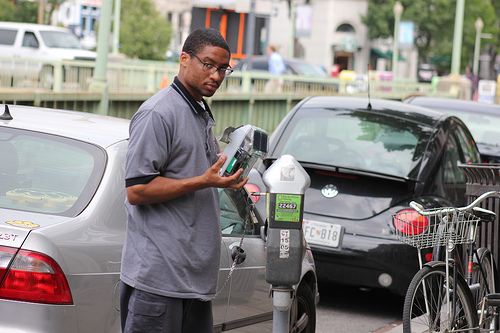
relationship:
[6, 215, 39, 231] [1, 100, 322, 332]
paw sticker on trunk of car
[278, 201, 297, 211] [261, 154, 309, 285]
numbers on front of parking meter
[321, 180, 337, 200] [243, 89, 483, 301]
logo on back of car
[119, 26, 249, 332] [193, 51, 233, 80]
man wearing glasses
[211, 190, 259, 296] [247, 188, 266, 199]
chain attached to key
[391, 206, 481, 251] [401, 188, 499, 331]
basket on front of bicycle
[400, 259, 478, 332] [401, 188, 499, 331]
tire on bottom of bicycle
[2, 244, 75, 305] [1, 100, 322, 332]
taillight on back of car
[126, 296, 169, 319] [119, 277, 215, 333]
pocket flap on side of pants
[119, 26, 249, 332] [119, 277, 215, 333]
man wearing pants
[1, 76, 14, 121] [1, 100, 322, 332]
antenna on top of car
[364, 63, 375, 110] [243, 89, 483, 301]
antenna on top of car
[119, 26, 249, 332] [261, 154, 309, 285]
man collecting money at parking meter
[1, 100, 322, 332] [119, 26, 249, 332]
car parked behind man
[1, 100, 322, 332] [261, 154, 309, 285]
car parked behind parking meter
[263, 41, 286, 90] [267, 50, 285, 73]
man wearing shirt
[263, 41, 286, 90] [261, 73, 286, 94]
man wearing pants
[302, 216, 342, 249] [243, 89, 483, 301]
license plate on back of car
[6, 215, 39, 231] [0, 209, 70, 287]
paw sticker on top of trunk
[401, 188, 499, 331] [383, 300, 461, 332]
bicycle on top of sidewalk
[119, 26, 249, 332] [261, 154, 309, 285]
man checking parking meter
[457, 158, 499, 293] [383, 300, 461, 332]
trashcan on top of sidewalk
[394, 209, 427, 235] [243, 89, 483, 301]
brake light on back of car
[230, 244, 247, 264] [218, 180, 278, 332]
handle on side of door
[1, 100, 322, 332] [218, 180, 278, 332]
car has door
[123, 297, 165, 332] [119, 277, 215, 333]
pocket on side of pants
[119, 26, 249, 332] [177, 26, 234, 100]
man has head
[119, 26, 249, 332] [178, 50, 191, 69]
man has ear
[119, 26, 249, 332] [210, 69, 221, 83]
man has nose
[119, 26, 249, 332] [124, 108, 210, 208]
man has arm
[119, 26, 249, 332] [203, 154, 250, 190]
man has hand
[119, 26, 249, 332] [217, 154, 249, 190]
man has fingers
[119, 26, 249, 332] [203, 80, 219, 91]
man has mouth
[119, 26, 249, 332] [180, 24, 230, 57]
man has hair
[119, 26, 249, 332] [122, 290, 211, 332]
man has legs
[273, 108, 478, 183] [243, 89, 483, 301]
windows on sides of car